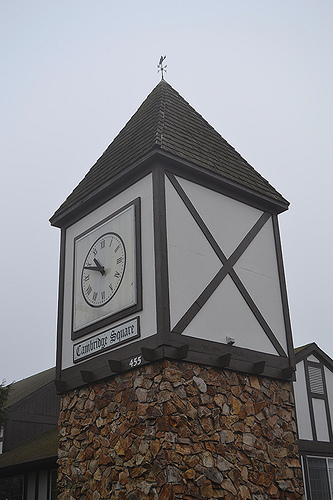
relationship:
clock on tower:
[69, 197, 142, 336] [21, 35, 322, 346]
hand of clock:
[89, 254, 104, 268] [63, 216, 144, 331]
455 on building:
[127, 354, 145, 369] [58, 82, 301, 494]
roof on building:
[5, 427, 60, 463] [2, 375, 55, 494]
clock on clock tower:
[69, 197, 142, 336] [47, 53, 298, 396]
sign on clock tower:
[73, 315, 143, 364] [47, 53, 298, 396]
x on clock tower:
[160, 168, 291, 357] [47, 53, 298, 396]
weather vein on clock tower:
[155, 52, 170, 79] [47, 53, 298, 396]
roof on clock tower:
[42, 75, 297, 216] [47, 53, 298, 396]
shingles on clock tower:
[105, 94, 229, 150] [47, 53, 298, 396]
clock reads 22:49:
[69, 197, 142, 336] [85, 244, 119, 280]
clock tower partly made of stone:
[47, 53, 298, 396] [61, 392, 297, 497]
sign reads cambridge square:
[73, 321, 143, 356] [78, 328, 137, 346]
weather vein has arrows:
[155, 52, 170, 79] [154, 64, 170, 73]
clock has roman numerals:
[69, 197, 142, 336] [84, 240, 124, 300]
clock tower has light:
[47, 53, 298, 396] [223, 334, 235, 347]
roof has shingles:
[42, 75, 297, 216] [97, 110, 227, 156]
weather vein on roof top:
[155, 52, 170, 79] [47, 78, 294, 204]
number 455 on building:
[127, 356, 147, 365] [58, 82, 301, 494]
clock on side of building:
[69, 197, 142, 336] [58, 82, 301, 494]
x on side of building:
[160, 168, 291, 357] [48, 51, 300, 500]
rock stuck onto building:
[191, 374, 207, 393] [1, 53, 323, 496]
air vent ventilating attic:
[306, 363, 322, 393] [292, 340, 322, 450]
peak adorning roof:
[309, 341, 317, 353] [294, 340, 322, 366]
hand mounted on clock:
[81, 264, 104, 271] [69, 197, 142, 336]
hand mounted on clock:
[89, 254, 104, 268] [69, 197, 142, 336]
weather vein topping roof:
[155, 52, 170, 79] [46, 77, 290, 228]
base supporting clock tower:
[55, 360, 305, 498] [47, 53, 298, 396]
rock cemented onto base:
[240, 429, 256, 446] [55, 360, 305, 498]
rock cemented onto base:
[191, 374, 207, 393] [55, 360, 305, 498]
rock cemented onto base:
[215, 452, 233, 470] [55, 360, 305, 498]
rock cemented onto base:
[114, 417, 130, 433] [55, 360, 305, 498]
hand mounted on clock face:
[81, 264, 104, 271] [79, 230, 127, 308]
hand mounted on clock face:
[90, 257, 105, 276] [79, 230, 127, 308]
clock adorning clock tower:
[69, 197, 142, 336] [47, 53, 298, 396]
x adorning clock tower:
[160, 168, 291, 357] [47, 53, 304, 498]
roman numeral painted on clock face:
[98, 238, 105, 250] [79, 230, 127, 308]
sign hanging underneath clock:
[73, 315, 143, 364] [69, 197, 142, 336]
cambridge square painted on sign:
[75, 323, 134, 356] [73, 315, 143, 364]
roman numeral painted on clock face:
[107, 282, 113, 291] [79, 230, 127, 308]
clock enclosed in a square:
[69, 245, 149, 336] [69, 217, 139, 341]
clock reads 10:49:
[69, 197, 142, 336] [57, 225, 124, 291]